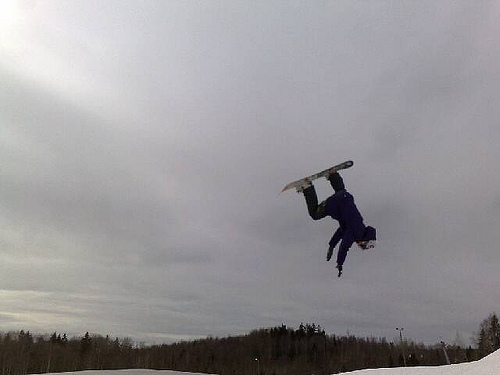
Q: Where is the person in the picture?
A: In the air.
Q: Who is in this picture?
A: A snowboarder jumping.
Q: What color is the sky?
A: White.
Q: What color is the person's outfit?
A: Black.